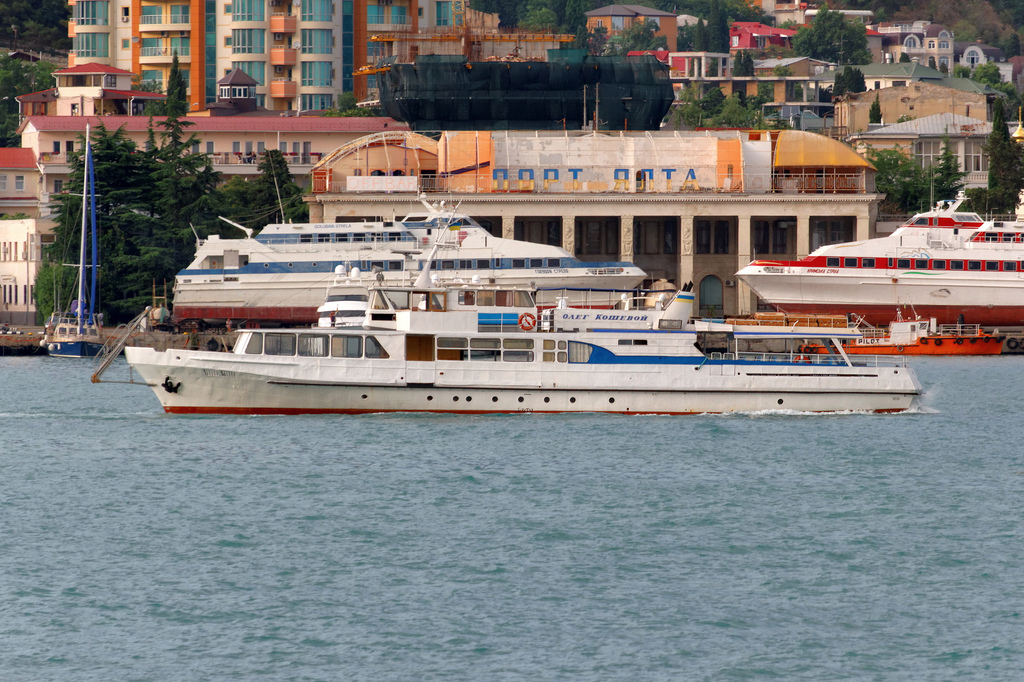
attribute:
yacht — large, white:
[169, 177, 597, 311]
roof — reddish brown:
[15, 111, 407, 137]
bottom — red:
[160, 402, 930, 418]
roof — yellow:
[773, 128, 879, 170]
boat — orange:
[799, 303, 992, 358]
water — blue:
[4, 346, 992, 679]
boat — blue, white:
[45, 122, 110, 360]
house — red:
[726, 18, 800, 60]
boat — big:
[730, 186, 992, 325]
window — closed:
[296, 26, 336, 57]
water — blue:
[280, 452, 873, 656]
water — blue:
[211, 446, 318, 524]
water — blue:
[49, 465, 484, 671]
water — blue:
[8, 420, 864, 671]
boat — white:
[126, 275, 926, 427]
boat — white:
[124, 260, 918, 429]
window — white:
[548, 340, 572, 373]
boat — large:
[126, 269, 934, 442]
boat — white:
[209, 217, 920, 542]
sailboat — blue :
[114, 266, 916, 496]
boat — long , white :
[136, 204, 867, 485]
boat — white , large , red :
[95, 271, 988, 533]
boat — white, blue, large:
[153, 236, 927, 524]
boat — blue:
[147, 217, 908, 540]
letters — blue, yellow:
[473, 109, 549, 207]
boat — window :
[259, 329, 298, 351]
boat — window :
[507, 351, 534, 364]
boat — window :
[509, 335, 531, 346]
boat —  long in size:
[123, 197, 932, 453]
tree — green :
[34, 109, 242, 311]